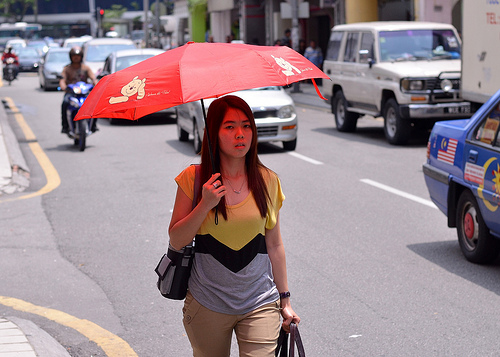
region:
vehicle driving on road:
[420, 73, 497, 266]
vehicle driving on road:
[322, 20, 466, 145]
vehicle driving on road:
[173, 93, 300, 155]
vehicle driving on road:
[75, 38, 131, 93]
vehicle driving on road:
[36, 49, 72, 89]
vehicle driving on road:
[6, 44, 40, 74]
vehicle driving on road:
[1, 37, 24, 64]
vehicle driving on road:
[58, 37, 85, 51]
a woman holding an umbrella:
[94, 8, 346, 265]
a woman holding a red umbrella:
[72, 15, 378, 330]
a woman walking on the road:
[33, 29, 469, 355]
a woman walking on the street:
[93, 41, 335, 345]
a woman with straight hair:
[103, 61, 331, 338]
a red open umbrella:
[93, 48, 383, 311]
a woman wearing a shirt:
[90, 75, 332, 341]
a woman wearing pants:
[164, 96, 321, 351]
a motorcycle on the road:
[12, 37, 164, 219]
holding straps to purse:
[274, 310, 309, 355]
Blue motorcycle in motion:
[55, 80, 94, 154]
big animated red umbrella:
[68, 38, 331, 125]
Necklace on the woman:
[222, 170, 251, 196]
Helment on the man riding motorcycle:
[65, 45, 85, 61]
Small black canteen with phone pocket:
[153, 242, 190, 304]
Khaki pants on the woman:
[172, 290, 285, 354]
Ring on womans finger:
[208, 179, 220, 191]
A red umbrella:
[132, 58, 226, 98]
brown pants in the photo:
[182, 313, 276, 353]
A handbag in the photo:
[272, 307, 309, 355]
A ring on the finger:
[201, 177, 220, 189]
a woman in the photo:
[172, 98, 307, 349]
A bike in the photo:
[54, 68, 109, 149]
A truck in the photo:
[347, 25, 441, 122]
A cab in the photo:
[391, 132, 496, 212]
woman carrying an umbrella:
[64, 25, 324, 350]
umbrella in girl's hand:
[73, 25, 345, 194]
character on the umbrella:
[96, 73, 163, 110]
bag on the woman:
[141, 218, 208, 314]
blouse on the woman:
[158, 154, 298, 308]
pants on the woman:
[181, 301, 283, 354]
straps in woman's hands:
[277, 315, 310, 355]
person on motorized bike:
[49, 43, 101, 144]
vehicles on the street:
[15, 30, 292, 157]